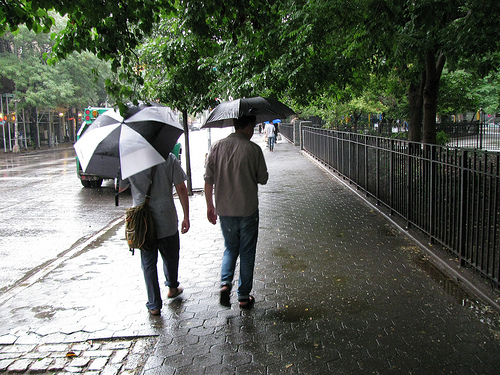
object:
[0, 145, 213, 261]
road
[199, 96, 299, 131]
grey umbrella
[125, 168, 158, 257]
bag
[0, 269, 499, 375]
ground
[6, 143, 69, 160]
curb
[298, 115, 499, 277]
black fence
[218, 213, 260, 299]
jeans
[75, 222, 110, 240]
water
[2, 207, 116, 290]
curb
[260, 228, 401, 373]
brick sidewalk